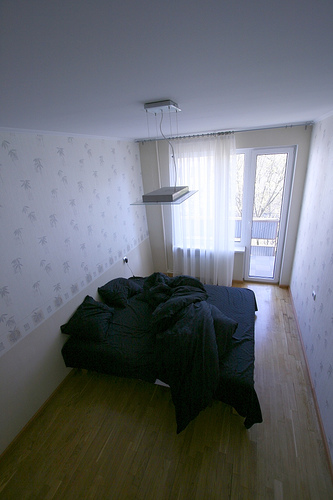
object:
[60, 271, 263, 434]
bed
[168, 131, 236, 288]
curtain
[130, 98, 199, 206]
light fixture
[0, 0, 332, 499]
bedroom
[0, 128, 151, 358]
wallpaper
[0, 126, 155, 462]
wall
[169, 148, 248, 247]
window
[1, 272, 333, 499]
floor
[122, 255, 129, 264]
outlet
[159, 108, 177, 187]
wires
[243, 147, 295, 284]
door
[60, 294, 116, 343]
pillow